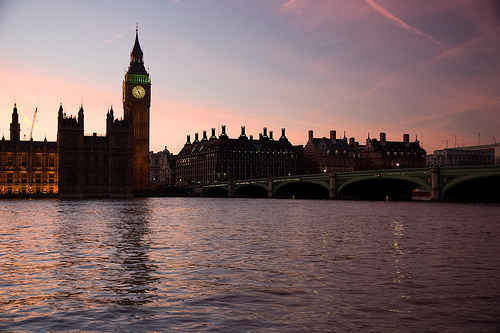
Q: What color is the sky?
A: Blue.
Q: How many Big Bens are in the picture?
A: One.